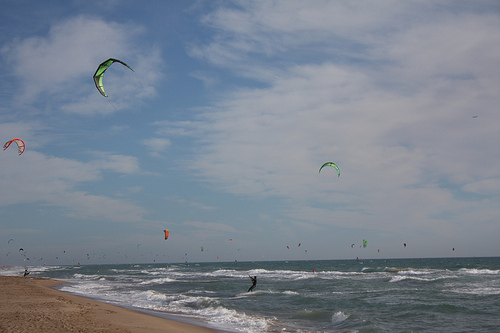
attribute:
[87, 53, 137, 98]
kite — green, red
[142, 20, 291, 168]
sky — blue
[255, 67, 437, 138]
clouds — white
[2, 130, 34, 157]
kite — red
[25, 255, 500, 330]
water — white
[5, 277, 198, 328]
beach — brown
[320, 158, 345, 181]
kite — blue